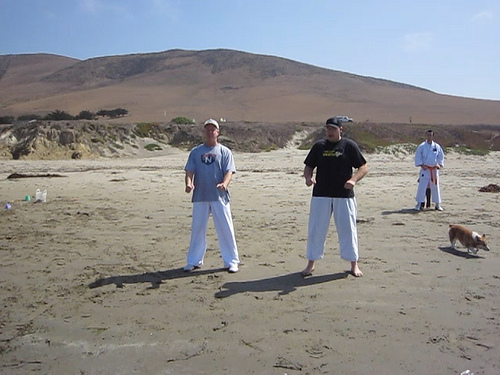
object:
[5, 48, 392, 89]
hilltop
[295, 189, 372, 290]
pants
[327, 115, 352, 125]
truck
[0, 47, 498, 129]
hill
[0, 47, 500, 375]
sand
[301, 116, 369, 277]
man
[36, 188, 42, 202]
bottle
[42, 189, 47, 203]
bottle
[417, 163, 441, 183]
belt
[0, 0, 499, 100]
sky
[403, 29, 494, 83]
cloud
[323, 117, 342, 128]
cap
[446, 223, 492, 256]
dog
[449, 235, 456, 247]
leg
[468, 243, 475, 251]
leg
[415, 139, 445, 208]
clothing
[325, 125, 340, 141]
head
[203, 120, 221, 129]
hat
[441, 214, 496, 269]
dog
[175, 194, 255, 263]
pant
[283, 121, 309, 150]
path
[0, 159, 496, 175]
road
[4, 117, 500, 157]
shore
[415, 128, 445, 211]
man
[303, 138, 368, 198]
black shirt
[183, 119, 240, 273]
man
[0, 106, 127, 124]
trees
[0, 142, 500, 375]
beach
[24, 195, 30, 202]
trash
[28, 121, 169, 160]
dunes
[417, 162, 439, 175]
mans waist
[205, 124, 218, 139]
head